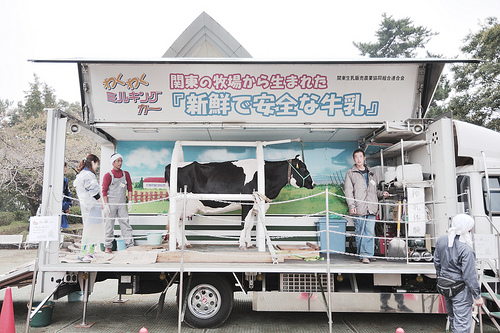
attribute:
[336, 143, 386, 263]
man — standing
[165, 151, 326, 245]
cow — black , white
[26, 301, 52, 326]
bucket — green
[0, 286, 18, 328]
cone — orange 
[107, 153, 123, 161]
headband — white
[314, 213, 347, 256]
trash can — blue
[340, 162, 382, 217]
coat — gray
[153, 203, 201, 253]
legs — back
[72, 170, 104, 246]
jacket — white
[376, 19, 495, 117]
tree — green 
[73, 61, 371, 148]
asian writing — red , blue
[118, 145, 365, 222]
scenary — painted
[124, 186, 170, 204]
fence — red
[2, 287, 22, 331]
cone — orange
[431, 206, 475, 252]
t-shirt — white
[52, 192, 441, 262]
fence — metal